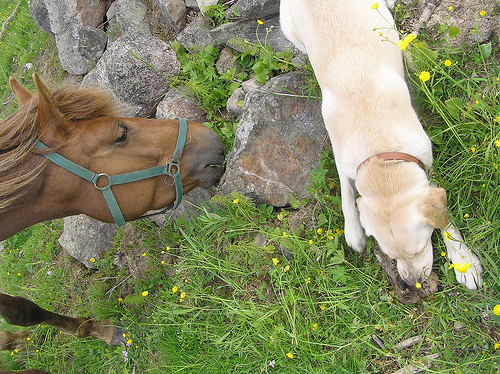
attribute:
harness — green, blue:
[25, 107, 198, 225]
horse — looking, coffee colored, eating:
[5, 68, 242, 250]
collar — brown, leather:
[348, 144, 429, 177]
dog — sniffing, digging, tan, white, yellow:
[274, 1, 493, 304]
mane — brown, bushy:
[0, 76, 120, 215]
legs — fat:
[0, 272, 132, 373]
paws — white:
[343, 232, 492, 297]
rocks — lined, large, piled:
[25, 0, 493, 271]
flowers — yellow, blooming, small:
[387, 8, 499, 184]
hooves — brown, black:
[90, 310, 153, 355]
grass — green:
[163, 37, 307, 148]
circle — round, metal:
[89, 169, 118, 192]